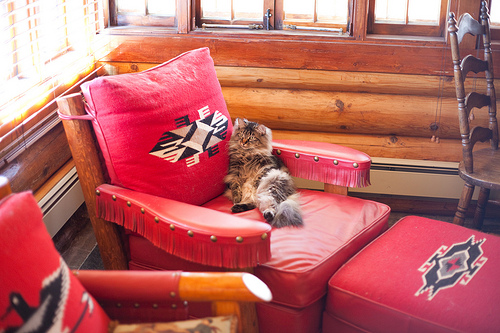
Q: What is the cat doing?
A: Resting in the chair.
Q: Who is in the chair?
A: A cat.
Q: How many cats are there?
A: 1.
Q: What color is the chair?
A: Red.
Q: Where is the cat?
A: In the chair.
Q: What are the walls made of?
A: Wood.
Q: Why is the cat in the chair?
A: It is resting.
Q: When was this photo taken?
A: During the day.